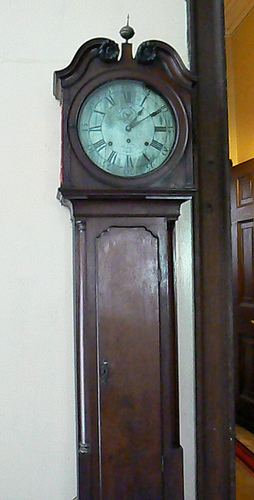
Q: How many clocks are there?
A: One.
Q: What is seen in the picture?
A: Clock.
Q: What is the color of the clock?
A: Brown.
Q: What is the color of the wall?
A: White.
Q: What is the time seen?
A: 1:10.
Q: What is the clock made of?
A: Wood.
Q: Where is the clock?
A: In the floor.